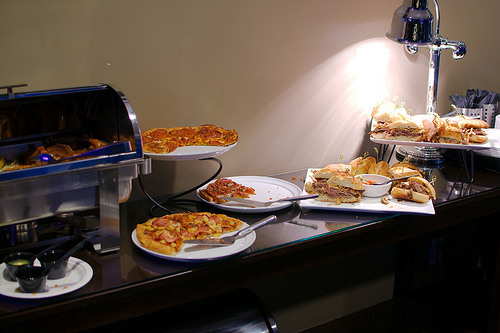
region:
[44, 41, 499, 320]
plates of food on a table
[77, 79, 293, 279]
plates of pizza on a table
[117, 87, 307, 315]
white plates of pizza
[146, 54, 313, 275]
pizza on white plates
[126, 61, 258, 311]
small pizza on plates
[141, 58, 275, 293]
small pizzas on white plate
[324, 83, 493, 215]
sandwiches on plate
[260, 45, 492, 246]
small sandwiches on a plate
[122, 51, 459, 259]
white plates on a table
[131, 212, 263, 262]
pizza on a white plate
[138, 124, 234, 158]
pizza on a white plate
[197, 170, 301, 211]
pizza on a white plate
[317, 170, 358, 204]
a sandwich on a platter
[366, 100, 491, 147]
a platter of sandwiches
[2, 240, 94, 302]
black cups on a white plate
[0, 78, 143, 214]
a warming tool for food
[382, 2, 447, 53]
top of a heat lamp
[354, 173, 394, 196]
a small white bowl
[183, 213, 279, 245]
a metal serving utensil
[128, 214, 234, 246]
pizza on the plate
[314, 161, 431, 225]
sandwiches on the tray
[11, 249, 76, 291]
three cups of sauce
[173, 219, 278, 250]
silver server on the plate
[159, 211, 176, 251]
pepperoni on the pizza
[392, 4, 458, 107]
warming light on the sandwiches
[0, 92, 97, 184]
roasting oven with spoon in it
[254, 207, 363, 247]
glass table top to serve food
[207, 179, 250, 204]
one single peice of pizza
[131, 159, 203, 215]
wires to warm food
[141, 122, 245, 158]
pizza on the plate.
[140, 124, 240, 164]
slices of the pizza are missing.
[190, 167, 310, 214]
the plate is white.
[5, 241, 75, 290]
sauces in bowls.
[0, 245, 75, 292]
three bowls on the plate.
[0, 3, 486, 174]
the wall is tan.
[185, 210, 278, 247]
knife on the plate.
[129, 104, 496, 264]
food on the counter.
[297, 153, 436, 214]
sandwiches on the plate.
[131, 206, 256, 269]
pizza on a white tray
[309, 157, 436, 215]
sandwiches on a white try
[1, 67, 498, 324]
food on top of a glass countertop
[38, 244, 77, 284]
a black condiment cup on a white plate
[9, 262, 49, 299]
a black condiment cup on a white plate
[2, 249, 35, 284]
a black mustard cup on a white plate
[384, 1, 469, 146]
a light on above a table of food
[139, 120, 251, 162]
a pizza on a white tray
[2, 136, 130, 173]
food inside a warming tray on a glass top table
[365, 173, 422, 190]
a spoon in a white bowel